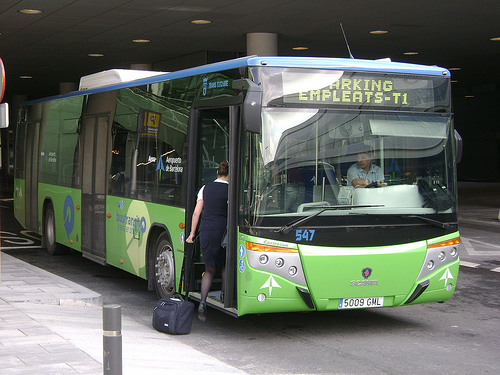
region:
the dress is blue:
[176, 172, 258, 287]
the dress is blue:
[190, 172, 228, 289]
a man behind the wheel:
[339, 126, 388, 225]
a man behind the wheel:
[323, 140, 401, 241]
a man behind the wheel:
[310, 115, 424, 261]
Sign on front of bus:
[279, 66, 428, 117]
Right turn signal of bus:
[239, 235, 305, 264]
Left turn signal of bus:
[420, 231, 462, 253]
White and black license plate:
[335, 290, 390, 311]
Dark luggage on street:
[138, 287, 202, 344]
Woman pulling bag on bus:
[147, 228, 216, 346]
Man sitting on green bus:
[336, 139, 401, 198]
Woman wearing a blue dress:
[188, 173, 230, 294]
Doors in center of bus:
[70, 107, 117, 270]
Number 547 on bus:
[290, 225, 322, 247]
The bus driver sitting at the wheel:
[344, 150, 388, 189]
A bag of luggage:
[151, 296, 197, 333]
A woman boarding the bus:
[151, 160, 236, 335]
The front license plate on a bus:
[338, 296, 384, 308]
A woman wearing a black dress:
[187, 159, 234, 319]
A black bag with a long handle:
[151, 238, 198, 338]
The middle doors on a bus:
[78, 115, 113, 262]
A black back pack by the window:
[417, 176, 458, 213]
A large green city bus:
[16, 61, 462, 306]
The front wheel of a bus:
[151, 230, 179, 297]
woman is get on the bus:
[92, 102, 278, 348]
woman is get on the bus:
[136, 97, 240, 313]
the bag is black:
[132, 259, 207, 356]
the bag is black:
[144, 285, 229, 336]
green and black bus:
[53, 105, 430, 331]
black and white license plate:
[334, 285, 411, 312]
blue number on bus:
[279, 227, 321, 250]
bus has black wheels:
[149, 224, 194, 295]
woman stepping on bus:
[193, 149, 220, 321]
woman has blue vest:
[196, 171, 243, 238]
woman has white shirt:
[192, 176, 209, 205]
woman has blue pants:
[181, 210, 230, 282]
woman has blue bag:
[139, 269, 205, 341]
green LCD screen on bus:
[293, 68, 436, 126]